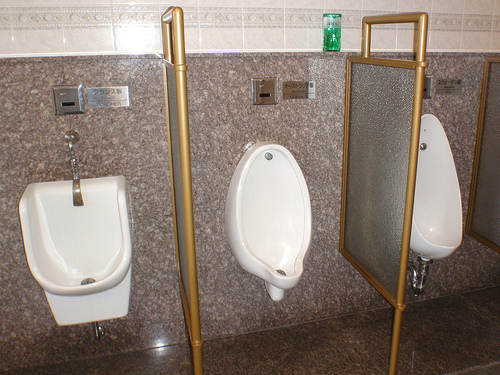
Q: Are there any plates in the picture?
A: Yes, there is a plate.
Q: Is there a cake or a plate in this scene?
A: Yes, there is a plate.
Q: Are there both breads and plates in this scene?
A: No, there is a plate but no breads.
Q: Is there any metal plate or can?
A: Yes, there is a metal plate.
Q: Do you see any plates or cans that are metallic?
A: Yes, the plate is metallic.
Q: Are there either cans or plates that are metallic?
A: Yes, the plate is metallic.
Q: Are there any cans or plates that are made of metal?
A: Yes, the plate is made of metal.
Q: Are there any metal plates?
A: Yes, there is a plate that is made of metal.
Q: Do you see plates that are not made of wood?
A: Yes, there is a plate that is made of metal.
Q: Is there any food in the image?
A: No, there is no food.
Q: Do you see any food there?
A: No, there is no food.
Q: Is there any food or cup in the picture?
A: No, there are no food or cups.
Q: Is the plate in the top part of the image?
A: Yes, the plate is in the top of the image.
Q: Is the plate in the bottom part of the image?
A: No, the plate is in the top of the image.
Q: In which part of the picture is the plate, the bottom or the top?
A: The plate is in the top of the image.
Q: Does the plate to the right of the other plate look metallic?
A: Yes, the plate is metallic.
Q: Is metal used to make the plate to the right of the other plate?
A: Yes, the plate is made of metal.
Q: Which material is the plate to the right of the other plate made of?
A: The plate is made of metal.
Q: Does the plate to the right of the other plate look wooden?
A: No, the plate is metallic.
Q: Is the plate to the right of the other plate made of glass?
A: No, the plate is made of metal.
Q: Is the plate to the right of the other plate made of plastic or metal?
A: The plate is made of metal.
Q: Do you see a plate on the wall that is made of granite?
A: Yes, there is a plate on the wall.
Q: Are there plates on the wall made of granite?
A: Yes, there is a plate on the wall.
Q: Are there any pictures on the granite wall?
A: No, there is a plate on the wall.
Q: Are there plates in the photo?
A: Yes, there is a plate.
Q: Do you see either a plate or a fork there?
A: Yes, there is a plate.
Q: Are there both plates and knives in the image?
A: No, there is a plate but no knives.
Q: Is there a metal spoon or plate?
A: Yes, there is a metal plate.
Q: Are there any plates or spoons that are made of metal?
A: Yes, the plate is made of metal.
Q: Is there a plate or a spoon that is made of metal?
A: Yes, the plate is made of metal.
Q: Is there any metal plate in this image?
A: Yes, there is a metal plate.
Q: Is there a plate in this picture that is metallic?
A: Yes, there is a plate that is metallic.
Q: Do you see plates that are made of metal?
A: Yes, there is a plate that is made of metal.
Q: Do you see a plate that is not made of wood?
A: Yes, there is a plate that is made of metal.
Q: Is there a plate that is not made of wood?
A: Yes, there is a plate that is made of metal.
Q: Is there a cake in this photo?
A: No, there are no cakes.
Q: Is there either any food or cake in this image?
A: No, there are no cakes or food.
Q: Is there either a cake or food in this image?
A: No, there are no cakes or food.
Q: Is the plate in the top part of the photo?
A: Yes, the plate is in the top of the image.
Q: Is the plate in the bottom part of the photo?
A: No, the plate is in the top of the image.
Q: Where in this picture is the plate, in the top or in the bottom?
A: The plate is in the top of the image.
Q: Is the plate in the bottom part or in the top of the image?
A: The plate is in the top of the image.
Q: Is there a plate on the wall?
A: Yes, there is a plate on the wall.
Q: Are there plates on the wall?
A: Yes, there is a plate on the wall.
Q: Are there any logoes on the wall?
A: No, there is a plate on the wall.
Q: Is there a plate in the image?
A: Yes, there is a plate.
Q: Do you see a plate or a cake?
A: Yes, there is a plate.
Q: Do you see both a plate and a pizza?
A: No, there is a plate but no pizzas.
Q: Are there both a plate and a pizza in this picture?
A: No, there is a plate but no pizzas.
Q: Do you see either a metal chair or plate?
A: Yes, there is a metal plate.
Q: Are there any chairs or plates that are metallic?
A: Yes, the plate is metallic.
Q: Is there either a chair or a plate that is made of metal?
A: Yes, the plate is made of metal.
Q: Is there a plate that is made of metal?
A: Yes, there is a plate that is made of metal.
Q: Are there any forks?
A: No, there are no forks.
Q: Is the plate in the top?
A: Yes, the plate is in the top of the image.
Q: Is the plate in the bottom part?
A: No, the plate is in the top of the image.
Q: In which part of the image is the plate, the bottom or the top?
A: The plate is in the top of the image.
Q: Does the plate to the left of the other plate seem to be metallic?
A: Yes, the plate is metallic.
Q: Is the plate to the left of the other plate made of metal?
A: Yes, the plate is made of metal.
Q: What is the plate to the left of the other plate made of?
A: The plate is made of metal.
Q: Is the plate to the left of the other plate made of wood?
A: No, the plate is made of metal.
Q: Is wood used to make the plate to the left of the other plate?
A: No, the plate is made of metal.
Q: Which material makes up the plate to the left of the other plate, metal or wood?
A: The plate is made of metal.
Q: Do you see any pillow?
A: No, there are no pillows.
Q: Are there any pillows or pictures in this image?
A: No, there are no pillows or pictures.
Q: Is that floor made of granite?
A: Yes, the floor is made of granite.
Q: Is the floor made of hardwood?
A: No, the floor is made of granite.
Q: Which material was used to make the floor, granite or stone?
A: The floor is made of granite.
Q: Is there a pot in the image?
A: No, there are no pots.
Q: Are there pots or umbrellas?
A: No, there are no pots or umbrellas.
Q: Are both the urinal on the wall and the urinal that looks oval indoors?
A: Yes, both the urinal and the urinal are indoors.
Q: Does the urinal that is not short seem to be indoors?
A: Yes, the urinal is indoors.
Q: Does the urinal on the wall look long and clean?
A: Yes, the urinal is long and clean.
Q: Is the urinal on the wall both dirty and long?
A: No, the urinal is long but clean.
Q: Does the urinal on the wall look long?
A: Yes, the urinal is long.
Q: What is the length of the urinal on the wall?
A: The urinal is long.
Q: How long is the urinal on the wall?
A: The urinal is long.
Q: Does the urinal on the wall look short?
A: No, the urinal is long.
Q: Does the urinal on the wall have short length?
A: No, the urinal is long.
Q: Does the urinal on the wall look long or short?
A: The urinal is long.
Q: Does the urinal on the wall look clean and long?
A: Yes, the urinal is clean and long.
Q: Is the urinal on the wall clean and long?
A: Yes, the urinal is clean and long.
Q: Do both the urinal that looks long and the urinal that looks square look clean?
A: Yes, both the urinal and the urinal are clean.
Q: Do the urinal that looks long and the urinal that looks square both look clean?
A: Yes, both the urinal and the urinal are clean.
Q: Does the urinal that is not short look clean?
A: Yes, the urinal is clean.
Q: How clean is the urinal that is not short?
A: The urinal is clean.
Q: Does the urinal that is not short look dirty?
A: No, the urinal is clean.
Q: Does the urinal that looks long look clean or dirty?
A: The urinal is clean.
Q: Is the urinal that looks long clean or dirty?
A: The urinal is clean.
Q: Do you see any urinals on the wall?
A: Yes, there is a urinal on the wall.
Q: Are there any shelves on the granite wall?
A: No, there is a urinal on the wall.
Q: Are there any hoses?
A: No, there are no hoses.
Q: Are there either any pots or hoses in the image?
A: No, there are no hoses or pots.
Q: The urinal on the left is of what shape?
A: The urinal is square.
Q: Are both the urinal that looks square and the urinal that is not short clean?
A: Yes, both the urinal and the urinal are clean.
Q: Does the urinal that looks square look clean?
A: Yes, the urinal is clean.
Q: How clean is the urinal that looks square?
A: The urinal is clean.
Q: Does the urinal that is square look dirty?
A: No, the urinal is clean.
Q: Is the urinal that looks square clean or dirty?
A: The urinal is clean.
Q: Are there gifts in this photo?
A: No, there are no gifts.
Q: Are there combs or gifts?
A: No, there are no gifts or combs.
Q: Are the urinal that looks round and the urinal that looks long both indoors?
A: Yes, both the urinal and the urinal are indoors.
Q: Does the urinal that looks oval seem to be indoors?
A: Yes, the urinal is indoors.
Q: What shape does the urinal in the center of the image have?
A: The urinal has round shape.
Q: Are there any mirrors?
A: No, there are no mirrors.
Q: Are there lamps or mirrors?
A: No, there are no mirrors or lamps.